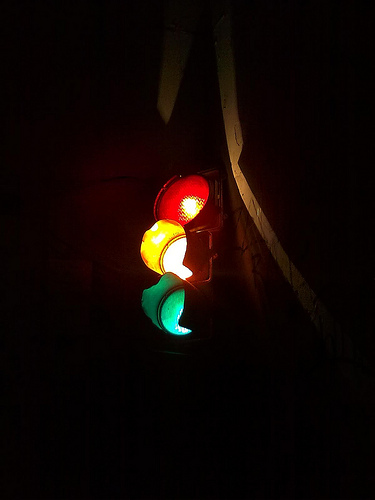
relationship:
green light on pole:
[139, 272, 204, 343] [150, 5, 347, 354]